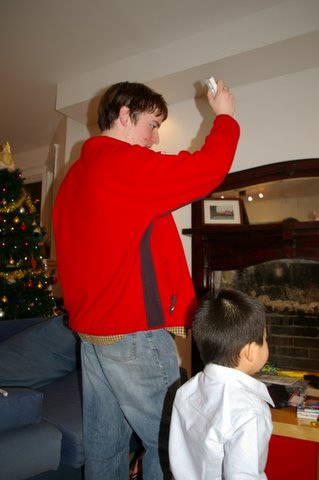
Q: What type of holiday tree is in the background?
A: Christmas tree.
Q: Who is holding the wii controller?
A: Tallest boy.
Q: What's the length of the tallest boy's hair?
A: Short.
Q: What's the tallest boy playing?
A: Wii game.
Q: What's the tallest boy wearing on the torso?
A: Jacket.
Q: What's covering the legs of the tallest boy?
A: Jeans.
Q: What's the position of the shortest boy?
A: Standing.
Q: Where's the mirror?
A: Above fireplae.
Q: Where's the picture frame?
A: On mantel.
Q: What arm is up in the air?
A: Right arm.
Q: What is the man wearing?
A: Shirt.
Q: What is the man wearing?
A: Red shirt.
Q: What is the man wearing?
A: Jeans.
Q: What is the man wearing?
A: Jacket.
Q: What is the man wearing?
A: Shirt.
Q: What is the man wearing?
A: Jeans.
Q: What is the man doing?
A: Standing.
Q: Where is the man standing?
A: Floor.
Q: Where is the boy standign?
A: Floor.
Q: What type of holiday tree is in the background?
A: A Christmas Tree.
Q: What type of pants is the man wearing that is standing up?
A: Jeans.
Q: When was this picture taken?
A: At Christmas.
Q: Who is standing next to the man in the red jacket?
A: A boy.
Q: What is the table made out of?
A: Wood.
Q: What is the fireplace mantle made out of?
A: Wood.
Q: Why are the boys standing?
A: They are playing a video game.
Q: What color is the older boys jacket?
A: Red.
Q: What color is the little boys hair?
A: Black.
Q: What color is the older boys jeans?
A: Blue.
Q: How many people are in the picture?
A: Two.